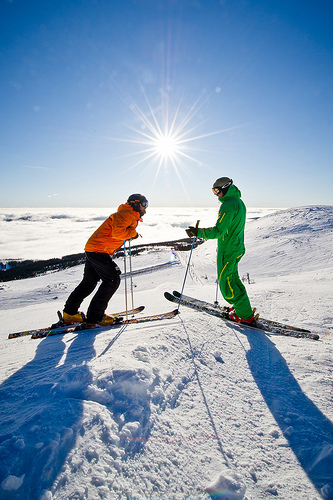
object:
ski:
[163, 290, 319, 341]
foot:
[228, 309, 254, 324]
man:
[61, 193, 149, 328]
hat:
[127, 193, 149, 218]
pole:
[129, 239, 135, 315]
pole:
[123, 240, 128, 322]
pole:
[215, 240, 218, 304]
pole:
[177, 219, 201, 311]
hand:
[185, 225, 197, 238]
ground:
[271, 350, 300, 423]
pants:
[63, 249, 122, 324]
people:
[184, 176, 259, 325]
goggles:
[211, 178, 233, 195]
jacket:
[196, 184, 247, 255]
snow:
[10, 353, 305, 498]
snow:
[270, 239, 312, 275]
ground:
[15, 279, 46, 307]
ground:
[271, 250, 290, 305]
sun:
[121, 96, 214, 188]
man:
[185, 176, 254, 325]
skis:
[163, 291, 319, 342]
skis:
[8, 305, 145, 340]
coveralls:
[197, 184, 253, 321]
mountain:
[0, 203, 333, 295]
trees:
[1, 236, 206, 282]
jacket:
[84, 202, 144, 257]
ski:
[7, 305, 179, 340]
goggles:
[135, 200, 149, 207]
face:
[139, 199, 148, 216]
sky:
[0, 2, 333, 213]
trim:
[218, 260, 235, 300]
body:
[85, 209, 137, 254]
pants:
[216, 247, 254, 322]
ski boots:
[226, 308, 254, 323]